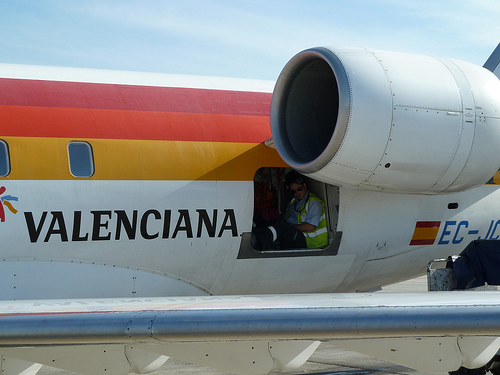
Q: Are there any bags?
A: Yes, there is a bag.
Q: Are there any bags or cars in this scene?
A: Yes, there is a bag.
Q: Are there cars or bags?
A: Yes, there is a bag.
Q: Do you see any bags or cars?
A: Yes, there is a bag.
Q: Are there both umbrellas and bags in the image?
A: No, there is a bag but no umbrellas.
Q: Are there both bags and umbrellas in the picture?
A: No, there is a bag but no umbrellas.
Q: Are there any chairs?
A: No, there are no chairs.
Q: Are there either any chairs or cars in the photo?
A: No, there are no chairs or cars.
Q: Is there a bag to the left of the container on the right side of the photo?
A: Yes, there is a bag to the left of the box.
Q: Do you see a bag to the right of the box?
A: No, the bag is to the left of the box.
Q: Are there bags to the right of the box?
A: No, the bag is to the left of the box.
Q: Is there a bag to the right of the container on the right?
A: No, the bag is to the left of the box.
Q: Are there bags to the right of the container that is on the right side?
A: No, the bag is to the left of the box.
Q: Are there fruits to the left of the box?
A: No, there is a bag to the left of the box.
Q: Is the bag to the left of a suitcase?
A: No, the bag is to the left of the box.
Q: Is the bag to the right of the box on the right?
A: No, the bag is to the left of the box.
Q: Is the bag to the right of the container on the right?
A: No, the bag is to the left of the box.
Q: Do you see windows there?
A: Yes, there is a window.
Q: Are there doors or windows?
A: Yes, there is a window.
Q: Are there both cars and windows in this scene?
A: No, there is a window but no cars.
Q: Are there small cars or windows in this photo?
A: Yes, there is a small window.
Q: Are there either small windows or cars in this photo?
A: Yes, there is a small window.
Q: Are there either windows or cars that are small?
A: Yes, the window is small.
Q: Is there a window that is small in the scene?
A: Yes, there is a small window.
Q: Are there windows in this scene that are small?
A: Yes, there is a window that is small.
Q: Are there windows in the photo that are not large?
A: Yes, there is a small window.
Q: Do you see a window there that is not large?
A: Yes, there is a small window.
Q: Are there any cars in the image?
A: No, there are no cars.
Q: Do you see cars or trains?
A: No, there are no cars or trains.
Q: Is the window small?
A: Yes, the window is small.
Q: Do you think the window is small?
A: Yes, the window is small.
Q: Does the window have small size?
A: Yes, the window is small.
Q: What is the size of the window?
A: The window is small.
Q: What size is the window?
A: The window is small.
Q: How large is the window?
A: The window is small.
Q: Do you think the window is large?
A: No, the window is small.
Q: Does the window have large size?
A: No, the window is small.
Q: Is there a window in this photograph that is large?
A: No, there is a window but it is small.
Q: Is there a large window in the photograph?
A: No, there is a window but it is small.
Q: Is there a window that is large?
A: No, there is a window but it is small.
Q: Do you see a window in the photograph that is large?
A: No, there is a window but it is small.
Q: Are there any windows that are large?
A: No, there is a window but it is small.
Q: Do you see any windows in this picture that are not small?
A: No, there is a window but it is small.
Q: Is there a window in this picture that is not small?
A: No, there is a window but it is small.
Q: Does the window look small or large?
A: The window is small.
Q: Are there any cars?
A: No, there are no cars.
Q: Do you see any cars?
A: No, there are no cars.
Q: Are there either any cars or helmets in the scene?
A: No, there are no cars or helmets.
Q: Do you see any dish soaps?
A: No, there are no dish soaps.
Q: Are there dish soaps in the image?
A: No, there are no dish soaps.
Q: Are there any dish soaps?
A: No, there are no dish soaps.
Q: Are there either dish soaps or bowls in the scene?
A: No, there are no dish soaps or bowls.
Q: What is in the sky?
A: The clouds are in the sky.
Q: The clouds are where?
A: The clouds are in the sky.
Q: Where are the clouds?
A: The clouds are in the sky.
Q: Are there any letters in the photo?
A: Yes, there are letters.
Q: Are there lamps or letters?
A: Yes, there are letters.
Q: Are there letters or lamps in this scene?
A: Yes, there are letters.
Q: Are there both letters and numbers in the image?
A: Yes, there are both letters and numbers.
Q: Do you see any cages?
A: No, there are no cages.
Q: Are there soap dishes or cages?
A: No, there are no cages or soap dishes.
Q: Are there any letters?
A: Yes, there are letters.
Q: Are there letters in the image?
A: Yes, there are letters.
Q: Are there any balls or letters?
A: Yes, there are letters.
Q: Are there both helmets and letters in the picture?
A: No, there are letters but no helmets.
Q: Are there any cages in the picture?
A: No, there are no cages.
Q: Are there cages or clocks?
A: No, there are no cages or clocks.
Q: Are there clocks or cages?
A: No, there are no cages or clocks.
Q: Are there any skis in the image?
A: No, there are no skis.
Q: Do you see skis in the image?
A: No, there are no skis.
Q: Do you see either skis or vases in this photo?
A: No, there are no skis or vases.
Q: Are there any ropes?
A: No, there are no ropes.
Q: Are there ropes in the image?
A: No, there are no ropes.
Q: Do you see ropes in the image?
A: No, there are no ropes.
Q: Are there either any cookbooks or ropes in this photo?
A: No, there are no ropes or cookbooks.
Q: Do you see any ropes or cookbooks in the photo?
A: No, there are no ropes or cookbooks.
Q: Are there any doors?
A: Yes, there is a door.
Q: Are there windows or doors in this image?
A: Yes, there is a door.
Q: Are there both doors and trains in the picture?
A: No, there is a door but no trains.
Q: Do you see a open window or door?
A: Yes, there is an open door.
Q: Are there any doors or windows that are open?
A: Yes, the door is open.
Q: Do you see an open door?
A: Yes, there is an open door.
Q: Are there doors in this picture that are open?
A: Yes, there is a door that is open.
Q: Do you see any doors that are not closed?
A: Yes, there is a open door.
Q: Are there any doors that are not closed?
A: Yes, there is a open door.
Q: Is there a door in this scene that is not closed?
A: Yes, there is a open door.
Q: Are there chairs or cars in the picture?
A: No, there are no cars or chairs.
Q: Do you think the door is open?
A: Yes, the door is open.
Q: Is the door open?
A: Yes, the door is open.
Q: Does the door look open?
A: Yes, the door is open.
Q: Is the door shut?
A: No, the door is open.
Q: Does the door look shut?
A: No, the door is open.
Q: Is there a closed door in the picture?
A: No, there is a door but it is open.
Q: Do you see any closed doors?
A: No, there is a door but it is open.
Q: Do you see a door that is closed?
A: No, there is a door but it is open.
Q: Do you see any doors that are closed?
A: No, there is a door but it is open.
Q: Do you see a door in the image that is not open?
A: No, there is a door but it is open.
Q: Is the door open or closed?
A: The door is open.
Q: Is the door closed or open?
A: The door is open.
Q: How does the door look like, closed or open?
A: The door is open.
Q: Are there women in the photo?
A: No, there are no women.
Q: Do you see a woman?
A: No, there are no women.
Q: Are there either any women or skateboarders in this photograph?
A: No, there are no women or skateboarders.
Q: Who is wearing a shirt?
A: The man is wearing a shirt.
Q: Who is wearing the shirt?
A: The man is wearing a shirt.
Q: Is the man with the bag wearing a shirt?
A: Yes, the man is wearing a shirt.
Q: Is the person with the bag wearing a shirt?
A: Yes, the man is wearing a shirt.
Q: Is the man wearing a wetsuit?
A: No, the man is wearing a shirt.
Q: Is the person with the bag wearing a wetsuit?
A: No, the man is wearing a shirt.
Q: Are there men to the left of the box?
A: Yes, there is a man to the left of the box.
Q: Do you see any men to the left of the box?
A: Yes, there is a man to the left of the box.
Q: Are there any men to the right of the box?
A: No, the man is to the left of the box.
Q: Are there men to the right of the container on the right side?
A: No, the man is to the left of the box.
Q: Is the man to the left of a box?
A: Yes, the man is to the left of a box.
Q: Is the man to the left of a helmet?
A: No, the man is to the left of a box.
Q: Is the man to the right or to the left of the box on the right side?
A: The man is to the left of the box.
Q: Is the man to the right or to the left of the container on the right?
A: The man is to the left of the box.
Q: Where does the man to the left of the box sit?
A: The man sits in the plane.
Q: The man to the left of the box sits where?
A: The man sits in the plane.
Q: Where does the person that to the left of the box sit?
A: The man sits in the plane.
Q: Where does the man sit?
A: The man sits in the plane.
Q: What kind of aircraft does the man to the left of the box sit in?
A: The man sits in the airplane.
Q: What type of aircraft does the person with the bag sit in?
A: The man sits in the airplane.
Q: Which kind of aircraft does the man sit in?
A: The man sits in the airplane.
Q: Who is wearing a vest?
A: The man is wearing a vest.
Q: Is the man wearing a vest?
A: Yes, the man is wearing a vest.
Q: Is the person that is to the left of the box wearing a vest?
A: Yes, the man is wearing a vest.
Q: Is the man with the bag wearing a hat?
A: No, the man is wearing a vest.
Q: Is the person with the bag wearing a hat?
A: No, the man is wearing a vest.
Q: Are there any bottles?
A: No, there are no bottles.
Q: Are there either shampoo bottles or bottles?
A: No, there are no bottles or shampoo bottles.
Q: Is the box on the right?
A: Yes, the box is on the right of the image.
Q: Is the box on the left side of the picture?
A: No, the box is on the right of the image.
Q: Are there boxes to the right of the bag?
A: Yes, there is a box to the right of the bag.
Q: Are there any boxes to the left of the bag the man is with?
A: No, the box is to the right of the bag.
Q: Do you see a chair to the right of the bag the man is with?
A: No, there is a box to the right of the bag.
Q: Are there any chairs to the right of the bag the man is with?
A: No, there is a box to the right of the bag.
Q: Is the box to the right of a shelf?
A: No, the box is to the right of the bag.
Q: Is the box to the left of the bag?
A: No, the box is to the right of the bag.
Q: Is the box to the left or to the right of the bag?
A: The box is to the right of the bag.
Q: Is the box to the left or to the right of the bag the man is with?
A: The box is to the right of the bag.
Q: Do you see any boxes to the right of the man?
A: Yes, there is a box to the right of the man.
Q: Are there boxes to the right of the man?
A: Yes, there is a box to the right of the man.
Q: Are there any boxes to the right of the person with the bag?
A: Yes, there is a box to the right of the man.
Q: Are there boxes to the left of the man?
A: No, the box is to the right of the man.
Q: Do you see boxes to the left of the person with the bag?
A: No, the box is to the right of the man.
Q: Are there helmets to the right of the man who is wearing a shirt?
A: No, there is a box to the right of the man.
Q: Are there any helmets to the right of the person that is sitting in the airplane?
A: No, there is a box to the right of the man.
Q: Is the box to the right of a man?
A: Yes, the box is to the right of a man.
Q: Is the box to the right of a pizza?
A: No, the box is to the right of a man.